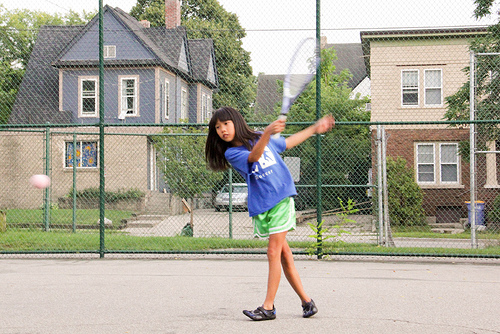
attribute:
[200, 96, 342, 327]
girl — playing, holding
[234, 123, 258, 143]
hair — long, dark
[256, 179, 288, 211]
shirt — blue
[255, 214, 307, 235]
shorts — green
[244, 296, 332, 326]
shoes — black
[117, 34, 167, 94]
fence — chain, gray, green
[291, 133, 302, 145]
skin — light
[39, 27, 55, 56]
roof — blue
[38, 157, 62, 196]
tennis ball — white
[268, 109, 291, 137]
hand — holding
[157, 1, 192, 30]
chimney — brown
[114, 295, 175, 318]
floor — court